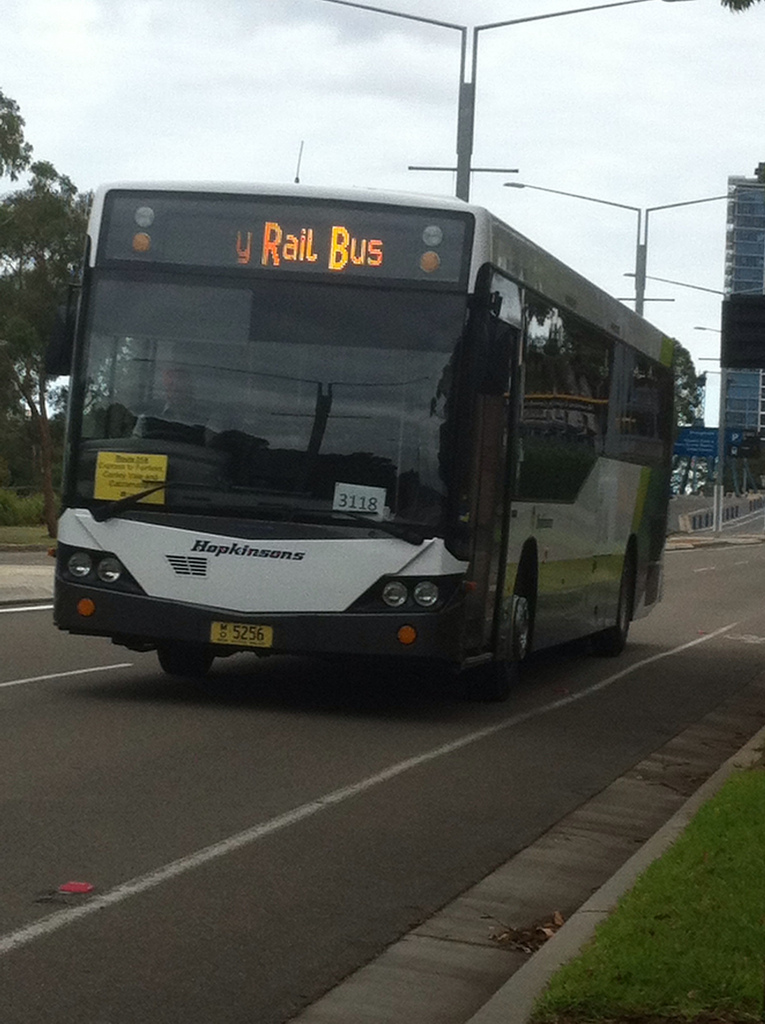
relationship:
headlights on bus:
[57, 543, 127, 591] [55, 137, 674, 701]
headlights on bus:
[374, 577, 450, 618] [55, 137, 674, 701]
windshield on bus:
[52, 258, 483, 536] [39, 178, 705, 717]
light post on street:
[493, 178, 746, 315] [5, 492, 760, 1021]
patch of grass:
[617, 917, 747, 993] [531, 764, 760, 1021]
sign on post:
[669, 421, 723, 466] [707, 422, 729, 537]